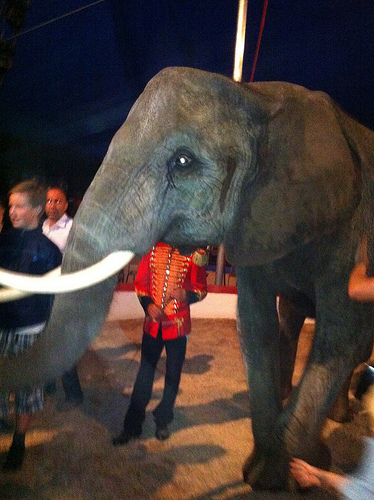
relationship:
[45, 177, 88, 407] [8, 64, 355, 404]
man around elephant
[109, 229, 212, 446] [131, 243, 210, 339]
man wearing a red coat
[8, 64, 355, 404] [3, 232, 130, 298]
elephant with tusks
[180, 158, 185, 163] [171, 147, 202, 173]
light on elephant eye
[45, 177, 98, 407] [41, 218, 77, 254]
man in a white shirt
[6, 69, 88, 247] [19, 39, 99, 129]
wall with a boarder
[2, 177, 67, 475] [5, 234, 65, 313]
boy wearing a jacket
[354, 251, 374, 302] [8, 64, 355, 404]
person touching elephant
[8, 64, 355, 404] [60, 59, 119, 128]
elephant at a circus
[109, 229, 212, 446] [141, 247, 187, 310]
man wearing a orange jacket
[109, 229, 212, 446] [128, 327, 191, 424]
man wearing pants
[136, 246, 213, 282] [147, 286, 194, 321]
arms and hands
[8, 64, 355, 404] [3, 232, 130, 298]
elephant has tusks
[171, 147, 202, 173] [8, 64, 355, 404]
eye ball of elephant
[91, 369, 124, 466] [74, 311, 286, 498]
shadows on ground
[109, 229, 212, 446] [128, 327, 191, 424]
man has on pants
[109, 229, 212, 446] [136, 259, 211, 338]
man was on a red coat